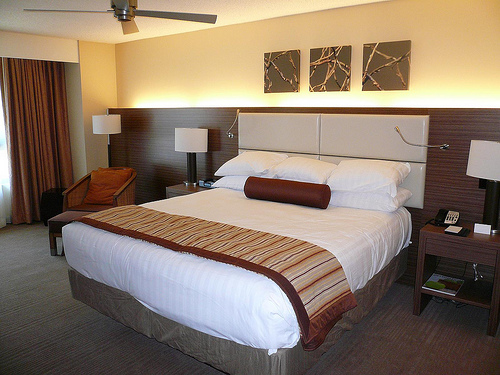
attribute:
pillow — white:
[327, 158, 412, 194]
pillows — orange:
[83, 163, 135, 206]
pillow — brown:
[242, 174, 331, 207]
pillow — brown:
[81, 164, 129, 206]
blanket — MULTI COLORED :
[78, 190, 352, 342]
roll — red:
[226, 162, 348, 212]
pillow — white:
[221, 146, 284, 194]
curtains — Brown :
[3, 56, 81, 226]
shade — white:
[91, 113, 122, 133]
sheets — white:
[58, 188, 413, 353]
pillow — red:
[243, 173, 330, 210]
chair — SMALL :
[48, 168, 131, 265]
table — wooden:
[412, 222, 498, 334]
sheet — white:
[66, 187, 412, 344]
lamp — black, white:
[161, 117, 217, 193]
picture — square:
[296, 34, 361, 88]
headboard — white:
[236, 112, 430, 212]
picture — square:
[363, 41, 412, 91]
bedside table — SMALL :
[410, 215, 499, 327]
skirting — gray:
[61, 264, 275, 369]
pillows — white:
[206, 147, 420, 217]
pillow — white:
[234, 145, 305, 182]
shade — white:
[457, 128, 497, 189]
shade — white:
[174, 117, 212, 158]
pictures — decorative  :
[261, 30, 413, 104]